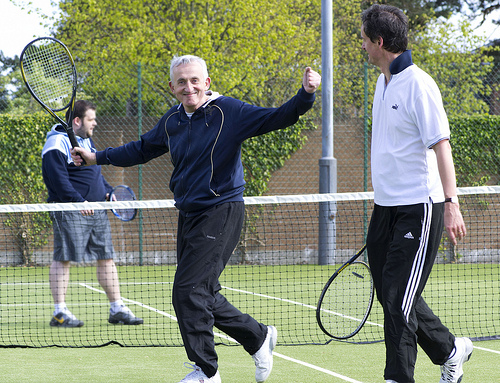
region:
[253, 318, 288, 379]
a white tennis shoe on a man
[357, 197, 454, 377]
black pants with white stripes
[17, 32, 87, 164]
a grey and yellow tennis racket in a man's hand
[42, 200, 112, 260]
grey shorts on a man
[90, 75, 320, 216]
a blue jacket on a man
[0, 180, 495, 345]
a tennis net on a court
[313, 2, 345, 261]
a tall metal pole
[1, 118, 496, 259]
a brick wall behind a fence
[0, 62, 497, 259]
a chain link fence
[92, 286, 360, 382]
a white line on a tennis court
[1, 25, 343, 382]
happy man playing tennis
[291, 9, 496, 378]
man walking on a tennis court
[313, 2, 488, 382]
man in a white shirt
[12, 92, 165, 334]
man wearing shorts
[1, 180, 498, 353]
tennis net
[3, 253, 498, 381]
green tennis court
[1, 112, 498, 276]
red brick wall with vines on it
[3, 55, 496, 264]
fence with green posts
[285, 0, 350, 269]
metal light post with a rusty bolt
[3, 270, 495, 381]
white lines on the tennis court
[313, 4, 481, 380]
The man is walking.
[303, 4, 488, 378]
The man is holding a tennis racket.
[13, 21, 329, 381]
The man is smiling.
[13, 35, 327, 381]
The man is happy.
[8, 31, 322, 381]
Man is holding tennis racket.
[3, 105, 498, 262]
Ivy growing on the briick wall.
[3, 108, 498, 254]
The ivy is green.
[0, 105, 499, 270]
The ivy is leafy.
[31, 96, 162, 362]
Man is standing on tennis court.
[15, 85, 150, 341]
Man is wearing a hoodie.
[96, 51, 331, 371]
man has arms outstretched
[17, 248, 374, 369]
tennis court is green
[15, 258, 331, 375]
white lines on tennis court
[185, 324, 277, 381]
man wears white shoes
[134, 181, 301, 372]
man has black pants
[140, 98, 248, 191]
man has blue shirt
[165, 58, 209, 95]
man has white hair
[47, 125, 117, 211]
man wears light blue coat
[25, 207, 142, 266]
man wears grey shorts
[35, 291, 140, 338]
man has grey shoes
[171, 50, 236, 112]
man is smiling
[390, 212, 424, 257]
addias logo on man's pants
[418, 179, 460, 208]
man is wearing a watch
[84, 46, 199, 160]
fence is green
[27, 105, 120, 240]
man is wearing a sweatshirt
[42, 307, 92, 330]
sneaker has a yellow nike check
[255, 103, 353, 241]
vines growing over the wall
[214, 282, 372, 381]
white lines on the tennis court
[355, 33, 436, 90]
man's collar is up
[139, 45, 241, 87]
man has grey hair